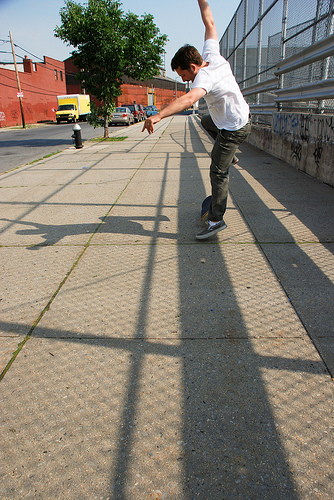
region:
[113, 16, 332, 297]
a man that is skateboarding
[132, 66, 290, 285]
a man on a skateboard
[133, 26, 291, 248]
a man on a sidewalk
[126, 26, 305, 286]
a man skateboarding on a sidewalk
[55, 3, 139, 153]
a tree on a sidewalk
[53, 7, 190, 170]
a sidewalk with trees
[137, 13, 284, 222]
a sidewalk with a man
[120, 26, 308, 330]
a sidewalk with a skateboarder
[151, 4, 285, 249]
a man wearing a white shirt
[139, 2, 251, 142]
The man is wearing a white shirt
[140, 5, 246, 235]
The man is skate boarding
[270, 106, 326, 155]
Blue and black graffiti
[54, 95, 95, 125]
The truck is yellow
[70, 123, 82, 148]
The fire hydrant is white and black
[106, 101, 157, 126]
Cars parked on the side of the street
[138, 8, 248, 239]
The man is wearing grey pants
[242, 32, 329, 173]
Grey wall with silver bars on top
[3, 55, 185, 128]
The building has red walls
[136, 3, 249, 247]
the man is on the side walk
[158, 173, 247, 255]
boy doing a trick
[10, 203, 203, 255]
shadow on the cement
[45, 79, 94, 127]
yellow truck across the street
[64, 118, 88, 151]
fire hydrant next to the tree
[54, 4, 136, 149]
tree on the sidewalk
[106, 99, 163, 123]
cars parked on the road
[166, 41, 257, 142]
boy has on a white t-shirt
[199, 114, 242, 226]
green pants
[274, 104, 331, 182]
graffiti on the wall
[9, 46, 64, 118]
builidng is red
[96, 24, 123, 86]
A tree in the photo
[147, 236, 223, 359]
A cabro paving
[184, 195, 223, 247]
Shoes in the photo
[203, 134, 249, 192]
Brown pants in the photo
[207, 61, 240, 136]
White shirt in the photo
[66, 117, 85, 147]
A water hydrant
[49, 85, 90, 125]
A truck in the photo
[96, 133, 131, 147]
Grass in the photo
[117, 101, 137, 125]
Cars in the photo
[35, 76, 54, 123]
A building in the photo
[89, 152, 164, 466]
sidewalk for pedestrians and skater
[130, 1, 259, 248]
skater on skate board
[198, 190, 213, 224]
skate board skater is on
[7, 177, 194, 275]
shadow of skate boarder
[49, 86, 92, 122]
yellow truck on street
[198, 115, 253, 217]
pants on skate boarder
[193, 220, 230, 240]
shoe on the skate boarder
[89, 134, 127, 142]
grass patch under tree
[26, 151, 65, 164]
grass along the curb